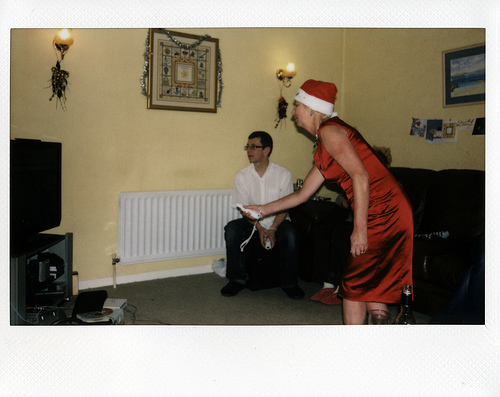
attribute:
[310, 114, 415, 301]
shirt — red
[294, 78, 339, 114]
hat — santa, red, white, christmas, santa claus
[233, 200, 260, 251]
remote — wii, white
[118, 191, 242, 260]
radiator — white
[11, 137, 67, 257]
tv — flat screen, here, black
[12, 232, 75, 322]
stand — grey, entertainment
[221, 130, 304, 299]
man — sitting down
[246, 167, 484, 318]
couch — here, leather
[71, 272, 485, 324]
carpet — light grey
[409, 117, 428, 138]
photo — here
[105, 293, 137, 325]
wii — white, video game, nintendo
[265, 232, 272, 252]
controller — wii, white, video game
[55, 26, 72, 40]
light — on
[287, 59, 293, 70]
light — on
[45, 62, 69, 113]
quilt — small